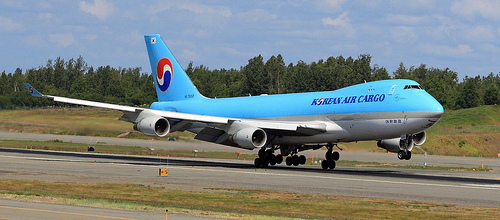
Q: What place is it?
A: It is a runway.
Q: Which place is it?
A: It is a runway.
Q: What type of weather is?
A: It is cloudy.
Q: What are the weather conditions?
A: It is cloudy.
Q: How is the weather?
A: It is cloudy.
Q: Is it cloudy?
A: Yes, it is cloudy.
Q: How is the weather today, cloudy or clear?
A: It is cloudy.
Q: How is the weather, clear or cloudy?
A: It is cloudy.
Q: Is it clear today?
A: No, it is cloudy.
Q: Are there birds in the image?
A: No, there are no birds.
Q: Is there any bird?
A: No, there are no birds.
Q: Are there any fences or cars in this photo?
A: No, there are no cars or fences.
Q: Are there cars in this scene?
A: No, there are no cars.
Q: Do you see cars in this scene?
A: No, there are no cars.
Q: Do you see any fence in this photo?
A: No, there are no fences.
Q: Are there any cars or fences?
A: No, there are no fences or cars.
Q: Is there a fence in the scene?
A: No, there are no fences.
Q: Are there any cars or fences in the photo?
A: No, there are no fences or cars.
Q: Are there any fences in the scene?
A: No, there are no fences.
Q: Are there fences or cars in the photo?
A: No, there are no fences or cars.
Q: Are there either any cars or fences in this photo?
A: No, there are no fences or cars.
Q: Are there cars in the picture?
A: No, there are no cars.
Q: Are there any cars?
A: No, there are no cars.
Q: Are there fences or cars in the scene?
A: No, there are no cars or fences.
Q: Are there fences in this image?
A: No, there are no fences.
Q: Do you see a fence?
A: No, there are no fences.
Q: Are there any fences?
A: No, there are no fences.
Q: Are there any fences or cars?
A: No, there are no fences or cars.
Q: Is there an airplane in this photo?
A: Yes, there is an airplane.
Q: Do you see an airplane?
A: Yes, there is an airplane.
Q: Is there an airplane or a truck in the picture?
A: Yes, there is an airplane.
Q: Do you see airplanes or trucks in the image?
A: Yes, there is an airplane.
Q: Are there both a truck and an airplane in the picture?
A: No, there is an airplane but no trucks.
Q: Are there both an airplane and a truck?
A: No, there is an airplane but no trucks.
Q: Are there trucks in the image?
A: No, there are no trucks.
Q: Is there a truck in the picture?
A: No, there are no trucks.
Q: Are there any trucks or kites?
A: No, there are no trucks or kites.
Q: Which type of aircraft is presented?
A: The aircraft is an airplane.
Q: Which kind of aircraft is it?
A: The aircraft is an airplane.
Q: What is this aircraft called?
A: This is an airplane.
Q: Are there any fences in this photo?
A: No, there are no fences.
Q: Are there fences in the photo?
A: No, there are no fences.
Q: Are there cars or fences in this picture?
A: No, there are no fences or cars.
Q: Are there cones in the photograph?
A: No, there are no cones.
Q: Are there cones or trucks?
A: No, there are no cones or trucks.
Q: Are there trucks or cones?
A: No, there are no cones or trucks.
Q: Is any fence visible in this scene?
A: No, there are no fences.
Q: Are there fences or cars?
A: No, there are no fences or cars.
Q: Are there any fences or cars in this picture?
A: No, there are no cars or fences.